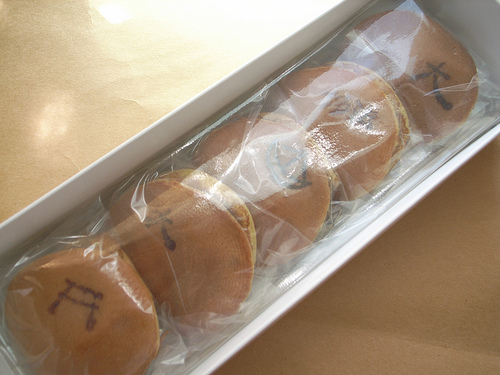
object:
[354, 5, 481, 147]
cake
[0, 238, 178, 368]
cake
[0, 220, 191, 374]
plastic wrapper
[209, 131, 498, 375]
ground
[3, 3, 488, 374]
pancake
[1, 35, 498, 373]
scene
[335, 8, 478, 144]
pancake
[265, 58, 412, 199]
pancake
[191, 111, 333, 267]
pancake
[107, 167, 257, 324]
pancake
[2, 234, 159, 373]
pancake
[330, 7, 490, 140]
pancake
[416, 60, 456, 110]
sign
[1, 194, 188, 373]
plastic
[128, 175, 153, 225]
lights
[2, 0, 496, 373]
tray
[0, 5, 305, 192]
paper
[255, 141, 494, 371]
paper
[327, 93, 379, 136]
chinese letter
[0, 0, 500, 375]
table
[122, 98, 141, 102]
line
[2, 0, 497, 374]
surface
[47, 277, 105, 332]
chinese letter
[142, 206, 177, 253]
chinese letter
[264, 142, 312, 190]
chinese letter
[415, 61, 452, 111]
chinese letter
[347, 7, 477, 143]
cale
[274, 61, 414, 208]
cale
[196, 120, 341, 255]
cale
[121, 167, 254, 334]
cale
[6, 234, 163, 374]
cale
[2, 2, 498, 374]
cardboard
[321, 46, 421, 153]
plastic wrapping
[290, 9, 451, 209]
plastic wrapping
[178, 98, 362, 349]
plastic wrapping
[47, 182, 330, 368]
plastic wrapping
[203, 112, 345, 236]
fortune cookie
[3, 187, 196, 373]
bag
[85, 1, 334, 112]
reflection